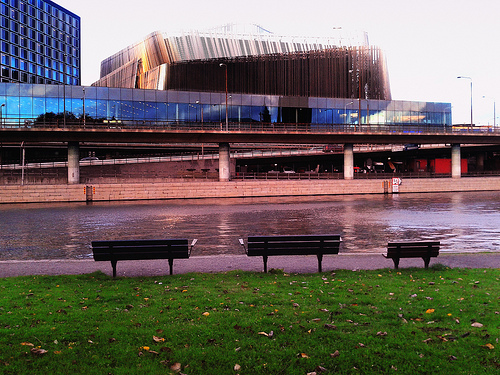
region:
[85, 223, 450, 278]
the benches are empty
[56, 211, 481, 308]
the benches are empty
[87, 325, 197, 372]
dry leaves on the ground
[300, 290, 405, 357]
dry leaves on the ground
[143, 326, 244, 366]
dry leaves on the ground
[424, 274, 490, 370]
dry leaves on the ground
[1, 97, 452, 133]
blue sky reflected in wall of windows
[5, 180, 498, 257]
red glow from sunset shines on wall and water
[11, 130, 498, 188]
a parking garage ramp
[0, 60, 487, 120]
tall street lights line roof top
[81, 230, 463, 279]
two adult benches and a toddler bench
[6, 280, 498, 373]
leaves strewn across the grass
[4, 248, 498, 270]
paved walkway along the water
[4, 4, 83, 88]
a taller office building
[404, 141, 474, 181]
red truck parked in garage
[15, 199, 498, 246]
garage reflected in the water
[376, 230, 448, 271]
bench near the grass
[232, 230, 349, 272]
bench near the grass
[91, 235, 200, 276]
bench near the grass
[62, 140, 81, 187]
support pillar to a bridge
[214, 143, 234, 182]
support pillar to a bridge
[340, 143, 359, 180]
support pillar to a bridge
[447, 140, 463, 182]
support pillar to a bridge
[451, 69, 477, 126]
street light near a building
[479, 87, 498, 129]
street light near a building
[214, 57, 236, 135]
street light near a building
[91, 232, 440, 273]
three empty banks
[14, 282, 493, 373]
very green grass in the field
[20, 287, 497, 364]
a lot of dry leaves in the field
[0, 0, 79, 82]
a blue majestic building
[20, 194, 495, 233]
a large quite lake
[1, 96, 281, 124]
a big blue window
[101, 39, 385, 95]
building with modern design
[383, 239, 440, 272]
a small bench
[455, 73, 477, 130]
a very high lamp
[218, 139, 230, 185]
a thick concrete column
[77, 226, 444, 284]
three benches in grass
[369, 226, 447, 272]
small child's bench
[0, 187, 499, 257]
body of water in front of sidewalk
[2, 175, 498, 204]
short brick wall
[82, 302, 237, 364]
brown leaves in grass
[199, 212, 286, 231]
ripples in body of water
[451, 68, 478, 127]
tall street lamp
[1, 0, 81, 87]
tall building with windows for walls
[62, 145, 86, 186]
stone pillar support beam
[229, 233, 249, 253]
wooden bench arm rail